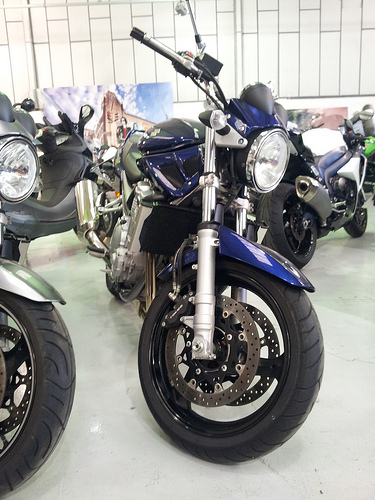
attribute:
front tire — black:
[0, 289, 78, 497]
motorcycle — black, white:
[1, 93, 88, 499]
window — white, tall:
[1, 3, 374, 100]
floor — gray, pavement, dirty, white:
[3, 191, 370, 498]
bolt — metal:
[224, 331, 234, 341]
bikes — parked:
[1, 0, 374, 499]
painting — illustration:
[30, 80, 179, 160]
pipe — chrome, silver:
[75, 177, 109, 254]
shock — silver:
[143, 256, 157, 309]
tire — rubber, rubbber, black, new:
[138, 256, 326, 462]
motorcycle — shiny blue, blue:
[67, 22, 342, 473]